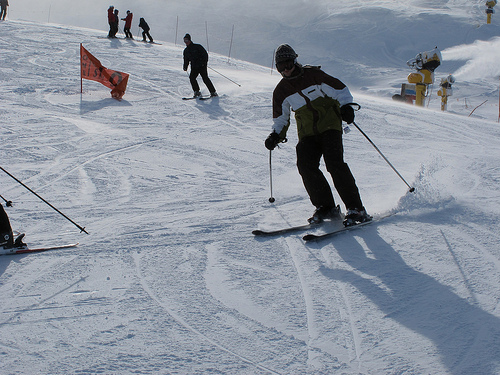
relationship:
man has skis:
[261, 46, 372, 223] [265, 114, 425, 210]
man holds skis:
[261, 46, 372, 223] [265, 114, 425, 210]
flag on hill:
[71, 46, 134, 98] [28, 23, 71, 101]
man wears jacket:
[261, 46, 372, 223] [263, 68, 358, 140]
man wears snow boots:
[261, 46, 372, 223] [308, 206, 369, 226]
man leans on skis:
[261, 46, 372, 223] [265, 114, 425, 210]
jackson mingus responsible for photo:
[367, 5, 411, 16] [0, 4, 499, 370]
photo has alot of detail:
[0, 4, 499, 370] [239, 14, 275, 24]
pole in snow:
[221, 16, 238, 64] [142, 249, 298, 324]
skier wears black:
[174, 30, 223, 101] [181, 45, 216, 96]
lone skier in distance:
[1, 1, 14, 26] [1, 6, 100, 27]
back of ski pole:
[3, 168, 94, 245] [10, 166, 94, 235]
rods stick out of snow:
[167, 10, 279, 79] [142, 249, 298, 324]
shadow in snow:
[318, 221, 498, 364] [142, 249, 298, 324]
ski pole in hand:
[264, 139, 283, 204] [260, 130, 282, 150]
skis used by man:
[265, 114, 425, 210] [261, 46, 372, 223]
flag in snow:
[71, 46, 134, 98] [142, 249, 298, 324]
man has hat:
[261, 46, 372, 223] [273, 46, 302, 66]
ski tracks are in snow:
[108, 213, 250, 250] [142, 249, 298, 324]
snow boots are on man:
[308, 206, 369, 226] [261, 46, 372, 223]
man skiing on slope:
[261, 46, 372, 223] [137, 119, 441, 312]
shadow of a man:
[318, 221, 498, 364] [261, 46, 372, 223]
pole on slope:
[221, 16, 238, 64] [137, 119, 441, 312]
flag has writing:
[71, 46, 134, 98] [86, 68, 128, 88]